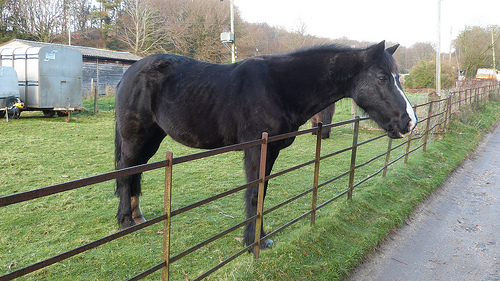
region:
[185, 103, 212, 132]
part of a horse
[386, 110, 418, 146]
part of a mouth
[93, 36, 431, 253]
A black horse looking over the fence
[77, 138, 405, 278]
A short fence in front of the horse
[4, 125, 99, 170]
Short green grass behind the horse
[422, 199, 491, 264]
Gray pavement in front of the fence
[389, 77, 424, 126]
A white patch on the horse's head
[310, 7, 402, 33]
The sky looks very bright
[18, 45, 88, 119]
An old grey trailer behind the horse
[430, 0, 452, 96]
A tall telephone pole in the field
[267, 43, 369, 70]
A short black mane on the horse's back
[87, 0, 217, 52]
A group of dead trees in the distance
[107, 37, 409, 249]
A black horse standing over the fence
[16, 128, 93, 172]
Short green grass grows behind the horse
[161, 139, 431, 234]
A small wooden fence in front of the horse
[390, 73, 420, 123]
A small white patch on the black horse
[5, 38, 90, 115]
An old grey trailer in the field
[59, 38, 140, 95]
An old house by the trees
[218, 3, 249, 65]
A large grey metal pole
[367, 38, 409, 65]
Two ears on the horse's head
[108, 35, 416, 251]
black horse standing by metal fence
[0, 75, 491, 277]
grassy area bordering road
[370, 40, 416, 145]
white stripe down middle of head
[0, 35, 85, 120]
curved silver trailers in back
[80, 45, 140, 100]
wooden building with short roof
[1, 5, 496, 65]
trees against gray skies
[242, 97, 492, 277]
edging of raised grass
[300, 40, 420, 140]
head and neck leaning over fence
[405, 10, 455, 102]
pole in front of wide bush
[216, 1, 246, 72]
pole with metal box behind horse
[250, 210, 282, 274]
part of a metal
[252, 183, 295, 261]
[part of a fence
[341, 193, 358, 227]
part of a grass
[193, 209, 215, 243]
part of a ground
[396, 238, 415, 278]
part of a floor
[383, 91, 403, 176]
part of a mouth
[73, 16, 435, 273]
this is a black horse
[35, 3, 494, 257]
horse standing in enclosure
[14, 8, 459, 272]
horse has head over fence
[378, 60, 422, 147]
white strip on horse nose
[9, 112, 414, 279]
fence railing is brown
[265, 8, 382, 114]
black mane on horse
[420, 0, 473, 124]
tall post in background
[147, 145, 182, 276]
Small brown wooden fence post in the grass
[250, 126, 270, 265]
Small brown wooden fence post in the grass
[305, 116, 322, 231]
Small brown wooden fence post in the grass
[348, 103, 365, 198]
Small brown wooden fence post in the grass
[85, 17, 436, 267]
Black and white horse standing in the grass